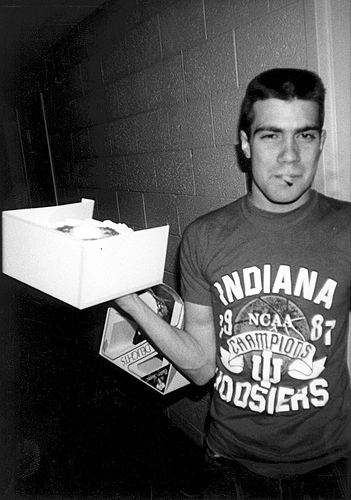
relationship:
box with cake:
[1, 194, 174, 311] [49, 211, 135, 237]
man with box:
[114, 66, 351, 500] [5, 187, 167, 309]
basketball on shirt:
[229, 281, 309, 389] [168, 187, 348, 481]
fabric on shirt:
[211, 262, 338, 416] [175, 200, 347, 442]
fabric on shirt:
[211, 262, 338, 416] [98, 176, 350, 448]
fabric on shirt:
[211, 262, 338, 416] [168, 187, 348, 481]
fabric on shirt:
[196, 255, 338, 421] [147, 159, 347, 483]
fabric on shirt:
[211, 262, 338, 416] [151, 196, 336, 476]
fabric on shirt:
[211, 262, 338, 416] [156, 190, 348, 431]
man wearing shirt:
[153, 66, 349, 494] [168, 187, 348, 481]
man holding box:
[114, 66, 351, 500] [0, 176, 209, 329]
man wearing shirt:
[114, 66, 351, 500] [168, 187, 348, 481]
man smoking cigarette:
[153, 66, 349, 494] [274, 169, 296, 195]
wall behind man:
[13, 0, 338, 225] [114, 66, 351, 500]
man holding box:
[114, 66, 351, 500] [1, 196, 171, 311]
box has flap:
[1, 196, 171, 311] [54, 196, 181, 294]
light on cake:
[71, 212, 115, 256] [35, 201, 158, 264]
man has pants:
[114, 66, 351, 500] [208, 457, 348, 497]